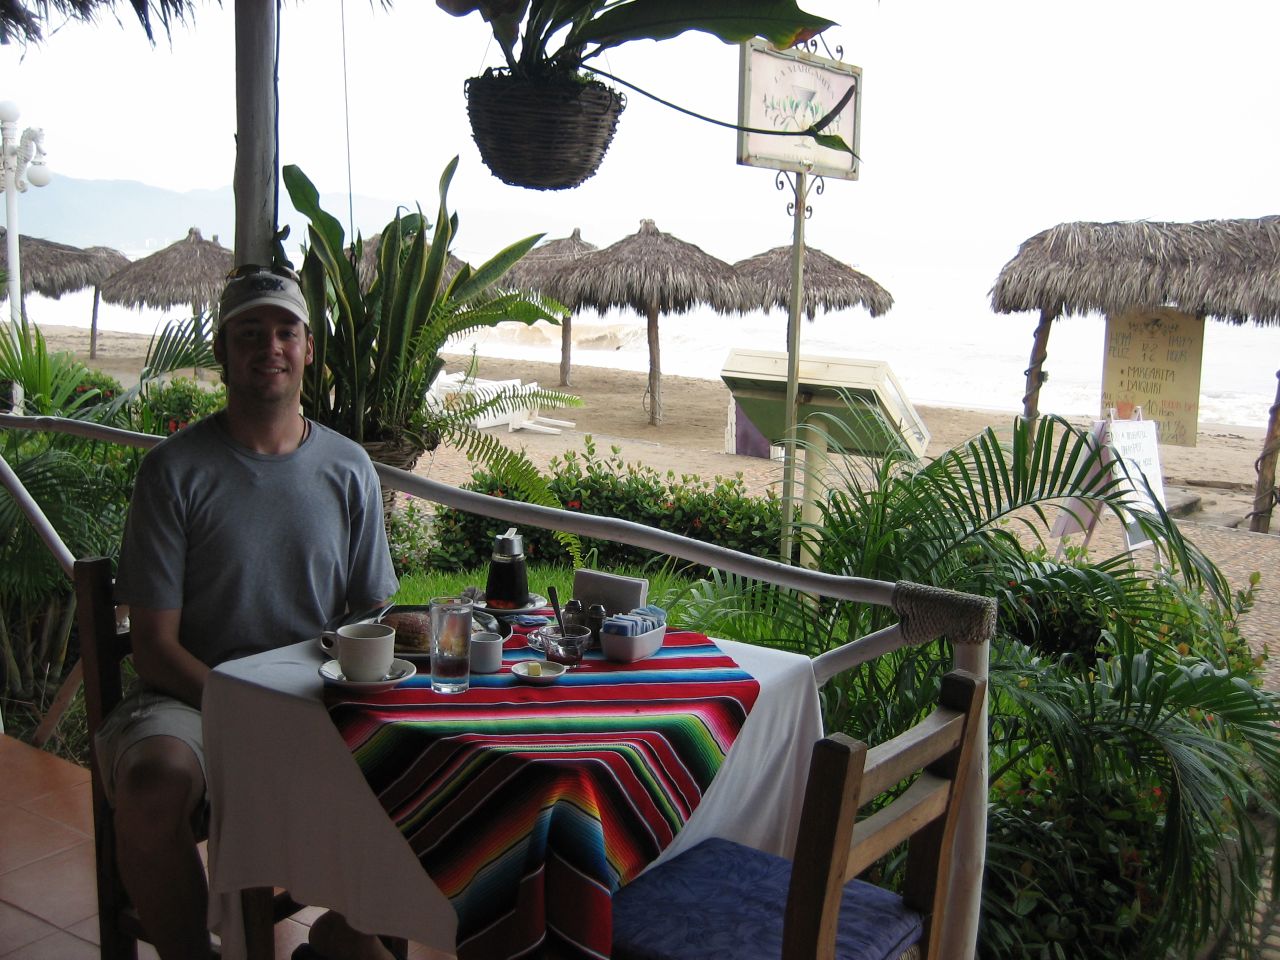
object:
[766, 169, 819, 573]
pole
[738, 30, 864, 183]
sign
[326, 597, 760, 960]
cloth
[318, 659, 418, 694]
saucer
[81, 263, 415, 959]
man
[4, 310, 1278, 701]
beach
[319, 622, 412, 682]
cup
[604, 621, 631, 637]
packets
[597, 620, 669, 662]
container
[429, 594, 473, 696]
glass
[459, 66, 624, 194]
basket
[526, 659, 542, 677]
butter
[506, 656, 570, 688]
dish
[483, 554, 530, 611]
syrup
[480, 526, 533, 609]
container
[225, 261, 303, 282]
sunglasses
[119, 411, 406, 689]
shirt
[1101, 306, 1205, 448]
sign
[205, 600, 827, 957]
table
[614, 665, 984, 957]
chair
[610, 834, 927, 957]
seat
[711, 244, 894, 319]
umbrella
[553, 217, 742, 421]
umbrella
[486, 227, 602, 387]
umbrella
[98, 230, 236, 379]
umbrella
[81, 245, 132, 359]
umbrella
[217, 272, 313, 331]
cap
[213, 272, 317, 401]
head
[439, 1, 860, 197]
plant